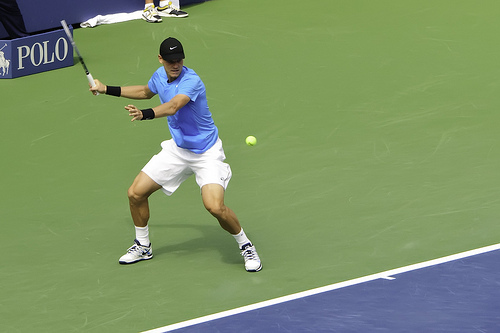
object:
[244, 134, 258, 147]
tennis ball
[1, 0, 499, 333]
tennis court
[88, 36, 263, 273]
man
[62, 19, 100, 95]
racket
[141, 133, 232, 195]
shorts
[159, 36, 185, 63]
cap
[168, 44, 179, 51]
nike logo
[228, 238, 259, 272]
shoes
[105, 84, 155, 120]
wristbands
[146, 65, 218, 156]
shirt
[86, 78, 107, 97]
right hand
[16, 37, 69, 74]
polo advertisement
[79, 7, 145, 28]
towel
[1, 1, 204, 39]
wall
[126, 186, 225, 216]
knees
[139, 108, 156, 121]
wrist band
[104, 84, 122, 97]
wrist band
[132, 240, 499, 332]
boundary line